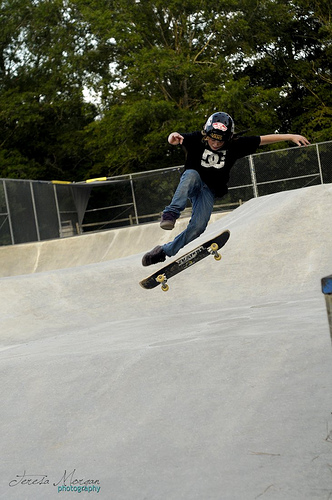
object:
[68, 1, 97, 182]
trees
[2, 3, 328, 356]
background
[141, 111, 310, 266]
boy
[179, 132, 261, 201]
t-shirt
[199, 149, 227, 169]
design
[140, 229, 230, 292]
skateboard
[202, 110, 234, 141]
helmet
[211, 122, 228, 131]
sticker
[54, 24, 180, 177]
tree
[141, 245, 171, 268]
shoes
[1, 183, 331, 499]
boarding area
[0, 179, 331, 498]
ground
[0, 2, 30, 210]
trees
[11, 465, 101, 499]
copyright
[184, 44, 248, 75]
ground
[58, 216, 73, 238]
trash can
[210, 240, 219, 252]
wheel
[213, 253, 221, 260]
wheel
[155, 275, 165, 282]
wheel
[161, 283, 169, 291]
wheel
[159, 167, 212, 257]
jeans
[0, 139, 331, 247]
fence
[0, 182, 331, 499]
park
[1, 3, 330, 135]
sky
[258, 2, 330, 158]
trees